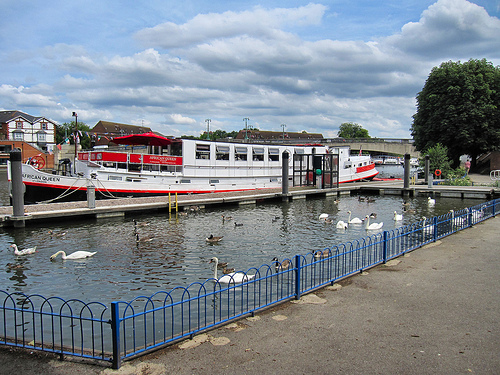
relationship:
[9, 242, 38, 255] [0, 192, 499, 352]
goose in water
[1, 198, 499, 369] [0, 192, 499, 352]
fence around water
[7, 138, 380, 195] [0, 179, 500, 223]
boat docked at pier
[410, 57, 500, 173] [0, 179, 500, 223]
tree behind pier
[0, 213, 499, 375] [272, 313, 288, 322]
concrete has stain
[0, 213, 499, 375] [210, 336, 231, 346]
concrete has stain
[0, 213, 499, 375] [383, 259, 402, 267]
concrete has stain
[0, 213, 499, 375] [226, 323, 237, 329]
concrete has stain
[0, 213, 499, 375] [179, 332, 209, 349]
concrete has stain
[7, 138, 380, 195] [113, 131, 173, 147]
boat has canopy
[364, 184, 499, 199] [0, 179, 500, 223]
dock attached to pier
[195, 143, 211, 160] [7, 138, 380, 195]
window on side of boat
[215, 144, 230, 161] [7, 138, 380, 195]
window on side of boat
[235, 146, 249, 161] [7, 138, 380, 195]
window on side of boat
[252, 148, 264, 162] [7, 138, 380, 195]
window on side of boat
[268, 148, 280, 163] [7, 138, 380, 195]
window on side of boat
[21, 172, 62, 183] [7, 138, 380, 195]
words on side of boat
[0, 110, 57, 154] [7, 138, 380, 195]
house behind boat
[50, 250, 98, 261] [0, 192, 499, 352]
swan in water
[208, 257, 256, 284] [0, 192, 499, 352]
swan in water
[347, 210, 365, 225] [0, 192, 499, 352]
swan in water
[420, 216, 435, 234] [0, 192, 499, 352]
swan in water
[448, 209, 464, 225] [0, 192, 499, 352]
swan in water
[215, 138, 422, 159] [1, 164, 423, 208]
bridge over water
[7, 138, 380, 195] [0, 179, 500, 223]
boat at pier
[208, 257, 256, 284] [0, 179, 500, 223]
swan near pier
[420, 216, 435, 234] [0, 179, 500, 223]
swan near pier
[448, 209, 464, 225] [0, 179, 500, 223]
swan near pier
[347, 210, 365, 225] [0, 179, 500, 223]
swan near pier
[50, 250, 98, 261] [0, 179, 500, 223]
swan near pier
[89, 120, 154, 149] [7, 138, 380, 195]
building behind boat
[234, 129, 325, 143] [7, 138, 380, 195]
building behind boat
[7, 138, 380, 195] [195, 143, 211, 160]
boat has window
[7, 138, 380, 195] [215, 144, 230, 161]
boat has window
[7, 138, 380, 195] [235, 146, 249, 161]
boat has window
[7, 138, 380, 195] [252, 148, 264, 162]
boat has window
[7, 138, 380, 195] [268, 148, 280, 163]
boat has window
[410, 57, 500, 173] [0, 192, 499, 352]
tree near water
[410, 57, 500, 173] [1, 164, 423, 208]
tree near water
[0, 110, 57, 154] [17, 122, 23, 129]
house has window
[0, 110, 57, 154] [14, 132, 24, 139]
house has window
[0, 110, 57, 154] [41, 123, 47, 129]
house has window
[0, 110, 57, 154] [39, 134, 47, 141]
house has window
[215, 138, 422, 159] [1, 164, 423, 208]
bridge near water